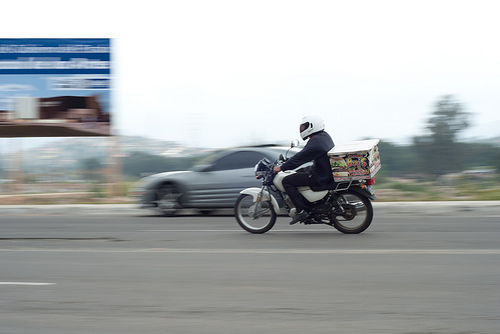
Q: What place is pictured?
A: It is a street.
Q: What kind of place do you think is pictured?
A: It is a street.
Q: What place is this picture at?
A: It is at the street.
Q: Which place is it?
A: It is a street.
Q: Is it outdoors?
A: Yes, it is outdoors.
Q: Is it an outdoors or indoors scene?
A: It is outdoors.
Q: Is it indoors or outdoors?
A: It is outdoors.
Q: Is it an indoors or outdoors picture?
A: It is outdoors.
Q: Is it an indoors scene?
A: No, it is outdoors.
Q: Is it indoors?
A: No, it is outdoors.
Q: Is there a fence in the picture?
A: No, there are no fences.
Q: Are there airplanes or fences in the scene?
A: No, there are no fences or airplanes.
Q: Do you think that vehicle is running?
A: Yes, the vehicle is running.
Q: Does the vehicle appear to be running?
A: Yes, the vehicle is running.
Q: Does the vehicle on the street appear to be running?
A: Yes, the vehicle is running.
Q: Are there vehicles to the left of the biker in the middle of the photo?
A: Yes, there is a vehicle to the left of the biker.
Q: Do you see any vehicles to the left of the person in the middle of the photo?
A: Yes, there is a vehicle to the left of the biker.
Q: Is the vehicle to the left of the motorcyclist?
A: Yes, the vehicle is to the left of the motorcyclist.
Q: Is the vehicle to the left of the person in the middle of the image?
A: Yes, the vehicle is to the left of the motorcyclist.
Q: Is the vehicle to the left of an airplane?
A: No, the vehicle is to the left of the motorcyclist.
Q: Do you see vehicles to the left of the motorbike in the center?
A: Yes, there is a vehicle to the left of the motorcycle.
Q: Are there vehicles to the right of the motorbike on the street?
A: No, the vehicle is to the left of the motorbike.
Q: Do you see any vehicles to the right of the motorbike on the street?
A: No, the vehicle is to the left of the motorbike.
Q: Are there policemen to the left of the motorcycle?
A: No, there is a vehicle to the left of the motorcycle.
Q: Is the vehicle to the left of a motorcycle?
A: Yes, the vehicle is to the left of a motorcycle.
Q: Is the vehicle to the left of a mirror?
A: No, the vehicle is to the left of a motorcycle.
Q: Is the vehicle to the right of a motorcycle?
A: No, the vehicle is to the left of a motorcycle.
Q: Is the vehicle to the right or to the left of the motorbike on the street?
A: The vehicle is to the left of the motorcycle.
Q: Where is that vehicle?
A: The vehicle is on the street.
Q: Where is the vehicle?
A: The vehicle is on the street.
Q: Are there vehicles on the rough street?
A: Yes, there is a vehicle on the street.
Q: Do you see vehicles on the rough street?
A: Yes, there is a vehicle on the street.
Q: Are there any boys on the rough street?
A: No, there is a vehicle on the street.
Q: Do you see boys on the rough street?
A: No, there is a vehicle on the street.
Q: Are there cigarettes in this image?
A: No, there are no cigarettes.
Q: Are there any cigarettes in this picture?
A: No, there are no cigarettes.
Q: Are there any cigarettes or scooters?
A: No, there are no cigarettes or scooters.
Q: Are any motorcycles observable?
A: Yes, there is a motorcycle.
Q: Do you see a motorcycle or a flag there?
A: Yes, there is a motorcycle.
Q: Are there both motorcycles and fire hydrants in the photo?
A: No, there is a motorcycle but no fire hydrants.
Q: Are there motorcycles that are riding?
A: Yes, there is a motorcycle that is riding.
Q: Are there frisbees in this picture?
A: No, there are no frisbees.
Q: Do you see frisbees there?
A: No, there are no frisbees.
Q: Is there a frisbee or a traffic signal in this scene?
A: No, there are no frisbees or traffic lights.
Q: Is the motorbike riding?
A: Yes, the motorbike is riding.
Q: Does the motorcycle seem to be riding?
A: Yes, the motorcycle is riding.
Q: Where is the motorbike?
A: The motorbike is on the street.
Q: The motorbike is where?
A: The motorbike is on the street.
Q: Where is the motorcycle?
A: The motorbike is on the street.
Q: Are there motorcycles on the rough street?
A: Yes, there is a motorcycle on the street.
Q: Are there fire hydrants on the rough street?
A: No, there is a motorcycle on the street.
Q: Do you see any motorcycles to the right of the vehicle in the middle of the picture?
A: Yes, there is a motorcycle to the right of the vehicle.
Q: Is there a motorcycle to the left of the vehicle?
A: No, the motorcycle is to the right of the vehicle.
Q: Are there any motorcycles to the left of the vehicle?
A: No, the motorcycle is to the right of the vehicle.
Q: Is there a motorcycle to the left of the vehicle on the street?
A: No, the motorcycle is to the right of the vehicle.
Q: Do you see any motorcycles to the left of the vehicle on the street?
A: No, the motorcycle is to the right of the vehicle.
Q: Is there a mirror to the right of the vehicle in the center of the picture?
A: No, there is a motorcycle to the right of the vehicle.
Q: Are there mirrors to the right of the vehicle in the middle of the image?
A: No, there is a motorcycle to the right of the vehicle.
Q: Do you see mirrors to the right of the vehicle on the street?
A: No, there is a motorcycle to the right of the vehicle.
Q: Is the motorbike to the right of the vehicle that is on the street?
A: Yes, the motorbike is to the right of the vehicle.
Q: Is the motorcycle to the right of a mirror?
A: No, the motorcycle is to the right of the vehicle.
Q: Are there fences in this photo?
A: No, there are no fences.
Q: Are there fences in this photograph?
A: No, there are no fences.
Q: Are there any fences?
A: No, there are no fences.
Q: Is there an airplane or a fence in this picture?
A: No, there are no fences or airplanes.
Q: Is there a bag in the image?
A: No, there are no bags.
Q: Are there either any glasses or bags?
A: No, there are no bags or glasses.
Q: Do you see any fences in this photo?
A: No, there are no fences.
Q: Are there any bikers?
A: Yes, there is a biker.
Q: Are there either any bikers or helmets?
A: Yes, there is a biker.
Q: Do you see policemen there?
A: No, there are no policemen.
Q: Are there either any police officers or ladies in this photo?
A: No, there are no police officers or ladies.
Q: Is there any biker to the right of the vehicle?
A: Yes, there is a biker to the right of the vehicle.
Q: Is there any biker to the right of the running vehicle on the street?
A: Yes, there is a biker to the right of the vehicle.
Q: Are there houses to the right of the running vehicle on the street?
A: No, there is a biker to the right of the vehicle.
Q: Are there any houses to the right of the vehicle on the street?
A: No, there is a biker to the right of the vehicle.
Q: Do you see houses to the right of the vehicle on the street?
A: No, there is a biker to the right of the vehicle.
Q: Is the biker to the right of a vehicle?
A: Yes, the biker is to the right of a vehicle.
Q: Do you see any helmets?
A: Yes, there is a helmet.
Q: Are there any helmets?
A: Yes, there is a helmet.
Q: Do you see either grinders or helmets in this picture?
A: Yes, there is a helmet.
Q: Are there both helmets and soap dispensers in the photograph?
A: No, there is a helmet but no soap dispensers.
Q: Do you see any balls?
A: No, there are no balls.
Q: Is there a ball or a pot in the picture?
A: No, there are no balls or pots.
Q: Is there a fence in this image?
A: No, there are no fences.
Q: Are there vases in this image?
A: No, there are no vases.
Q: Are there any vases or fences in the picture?
A: No, there are no vases or fences.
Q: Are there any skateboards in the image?
A: No, there are no skateboards.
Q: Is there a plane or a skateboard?
A: No, there are no skateboards or airplanes.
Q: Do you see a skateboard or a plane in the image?
A: No, there are no skateboards or airplanes.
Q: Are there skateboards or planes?
A: No, there are no skateboards or planes.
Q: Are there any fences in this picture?
A: No, there are no fences.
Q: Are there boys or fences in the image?
A: No, there are no fences or boys.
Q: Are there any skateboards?
A: No, there are no skateboards.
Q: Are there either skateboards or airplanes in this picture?
A: No, there are no skateboards or airplanes.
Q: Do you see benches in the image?
A: No, there are no benches.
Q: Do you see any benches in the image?
A: No, there are no benches.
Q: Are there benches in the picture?
A: No, there are no benches.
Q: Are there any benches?
A: No, there are no benches.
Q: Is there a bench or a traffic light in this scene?
A: No, there are no benches or traffic lights.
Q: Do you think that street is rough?
A: Yes, the street is rough.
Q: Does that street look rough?
A: Yes, the street is rough.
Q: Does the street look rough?
A: Yes, the street is rough.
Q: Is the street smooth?
A: No, the street is rough.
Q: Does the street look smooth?
A: No, the street is rough.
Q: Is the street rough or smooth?
A: The street is rough.